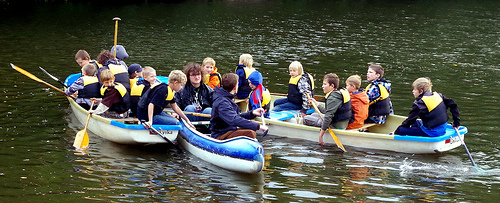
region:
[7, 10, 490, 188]
several canoeing kids in the water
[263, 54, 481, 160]
a canoe full of children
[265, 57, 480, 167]
children in life jackets in a canoe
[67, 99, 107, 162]
yellow oar for a canoe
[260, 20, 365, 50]
ripples in the water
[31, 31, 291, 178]
kids holding on to canoes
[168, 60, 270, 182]
blue and white canoe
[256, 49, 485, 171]
kids rowing and steering a canoe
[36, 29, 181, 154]
kids rowing a canoe on the river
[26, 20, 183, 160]
kids playing in a canoe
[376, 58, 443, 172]
child in life vest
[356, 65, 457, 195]
child in blue and yellow vest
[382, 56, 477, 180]
child at end of boat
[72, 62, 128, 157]
child with yellow oar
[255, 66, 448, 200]
children in blue and white boat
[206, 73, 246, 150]
person in blue jacket and brown pants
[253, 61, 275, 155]
end of an oar that is red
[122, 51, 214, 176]
boy leaning into a boat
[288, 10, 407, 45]
ripples on the water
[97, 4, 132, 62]
top of an oar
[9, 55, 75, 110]
paddle with yellow tip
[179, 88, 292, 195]
blue and white canoe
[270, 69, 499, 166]
blue and white boat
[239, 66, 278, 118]
boy wearing blue rain coat with hood up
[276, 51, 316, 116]
child wearing life persevere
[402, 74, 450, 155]
boy in yellow and blue life vest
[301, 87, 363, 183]
yellow paddle use to paddle boat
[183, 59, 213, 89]
boy with eye glasses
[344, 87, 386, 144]
orange coat with hood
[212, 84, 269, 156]
man wearing dark blue coat with hood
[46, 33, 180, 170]
a boat filled with lots of people.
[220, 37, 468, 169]
a blue and white boat with people in it.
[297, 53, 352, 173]
a wooden paddle.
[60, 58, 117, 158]
a yellow long paddle.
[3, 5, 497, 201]
a large body of water.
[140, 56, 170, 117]
a young blonde boy.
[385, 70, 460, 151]
a kid wearing a life vest.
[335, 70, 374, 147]
a boy in an orange jacket.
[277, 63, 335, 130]
a girl riding in a boat.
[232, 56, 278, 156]
a person sitting on a boat.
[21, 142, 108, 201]
water is clear and calm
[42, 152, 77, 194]
water is clear and calm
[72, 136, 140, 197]
water is clear and calm